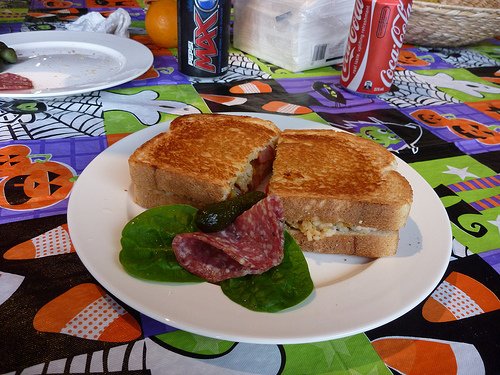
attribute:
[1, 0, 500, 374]
cloth — halloween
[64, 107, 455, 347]
plate — white, holding food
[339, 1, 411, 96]
can — coke, red, coca cola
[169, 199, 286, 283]
meat — pink, spotted, lunch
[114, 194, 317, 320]
leaf — green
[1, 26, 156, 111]
plate — nearly empty, white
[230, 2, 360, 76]
napkins — stacked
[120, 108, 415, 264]
sandwich — brown, toasted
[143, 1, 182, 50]
fruit — orange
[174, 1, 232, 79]
can — pepsi, red, black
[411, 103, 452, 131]
pumpkin — pictured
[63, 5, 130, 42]
napkin — used, white, crumpled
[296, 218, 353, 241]
fat — white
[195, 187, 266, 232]
pickle — green, small